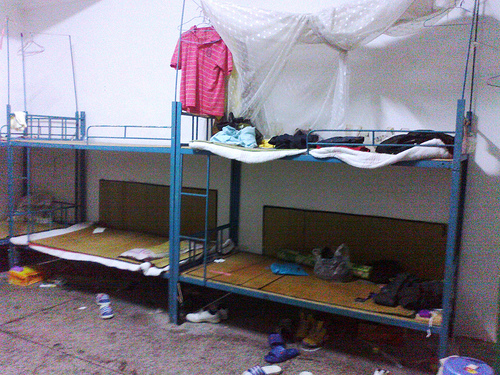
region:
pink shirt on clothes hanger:
[160, 22, 240, 115]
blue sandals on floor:
[266, 328, 296, 362]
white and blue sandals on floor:
[230, 364, 287, 373]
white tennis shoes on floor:
[188, 306, 239, 328]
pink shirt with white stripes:
[180, 31, 222, 103]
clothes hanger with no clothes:
[18, 30, 50, 68]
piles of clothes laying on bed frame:
[217, 118, 449, 161]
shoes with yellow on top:
[293, 310, 328, 353]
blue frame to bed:
[15, 110, 88, 154]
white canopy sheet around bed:
[263, 12, 467, 104]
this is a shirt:
[148, 16, 282, 138]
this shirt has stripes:
[160, 21, 267, 136]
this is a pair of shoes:
[254, 314, 301, 374]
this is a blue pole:
[442, 84, 469, 344]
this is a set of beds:
[13, 87, 495, 357]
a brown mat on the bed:
[215, 236, 425, 335]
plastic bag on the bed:
[294, 230, 361, 292]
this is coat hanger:
[173, 7, 216, 40]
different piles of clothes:
[208, 105, 442, 170]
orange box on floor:
[5, 247, 45, 295]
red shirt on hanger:
[156, 9, 234, 121]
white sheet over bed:
[220, 1, 430, 130]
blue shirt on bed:
[199, 105, 265, 152]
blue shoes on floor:
[256, 328, 297, 365]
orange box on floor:
[17, 254, 57, 305]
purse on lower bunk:
[300, 233, 365, 292]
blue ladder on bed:
[168, 120, 231, 290]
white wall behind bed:
[87, 21, 154, 115]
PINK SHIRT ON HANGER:
[168, 25, 239, 122]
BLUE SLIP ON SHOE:
[258, 343, 303, 365]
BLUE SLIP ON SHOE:
[265, 325, 285, 347]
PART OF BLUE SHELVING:
[442, 193, 460, 241]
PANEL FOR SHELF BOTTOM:
[316, 287, 357, 305]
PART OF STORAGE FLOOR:
[21, 305, 85, 361]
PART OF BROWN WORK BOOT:
[297, 314, 336, 352]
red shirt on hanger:
[162, 31, 251, 111]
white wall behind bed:
[101, 49, 144, 101]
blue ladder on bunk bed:
[155, 109, 209, 295]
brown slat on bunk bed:
[231, 235, 429, 315]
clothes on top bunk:
[268, 117, 428, 165]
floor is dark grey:
[94, 326, 176, 374]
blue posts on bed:
[134, 115, 219, 327]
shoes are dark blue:
[248, 327, 290, 367]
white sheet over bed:
[244, 16, 409, 131]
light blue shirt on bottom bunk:
[257, 244, 315, 290]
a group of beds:
[20, 48, 498, 369]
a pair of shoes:
[248, 317, 301, 373]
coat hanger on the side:
[19, 22, 50, 70]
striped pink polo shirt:
[169, 23, 234, 118]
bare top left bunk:
[12, 137, 174, 147]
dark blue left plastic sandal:
[264, 345, 296, 364]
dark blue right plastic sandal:
[265, 328, 283, 347]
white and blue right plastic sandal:
[240, 364, 280, 373]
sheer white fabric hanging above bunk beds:
[197, 0, 497, 175]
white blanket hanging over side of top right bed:
[190, 140, 450, 169]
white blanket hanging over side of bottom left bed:
[8, 220, 216, 277]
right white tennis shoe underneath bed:
[185, 309, 217, 324]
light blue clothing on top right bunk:
[207, 124, 258, 146]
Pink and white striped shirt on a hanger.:
[170, 23, 231, 116]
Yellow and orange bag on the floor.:
[5, 261, 47, 283]